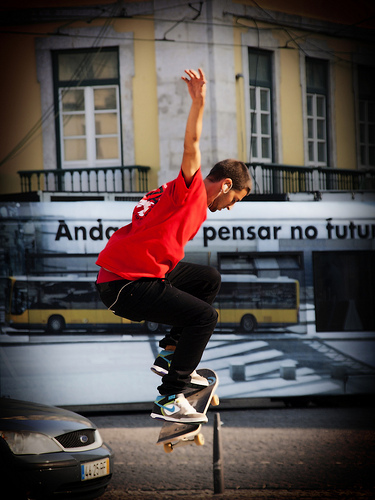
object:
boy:
[94, 65, 257, 425]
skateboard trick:
[140, 351, 234, 492]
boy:
[89, 66, 255, 455]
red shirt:
[95, 167, 209, 278]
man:
[92, 63, 264, 451]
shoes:
[147, 347, 211, 426]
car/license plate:
[76, 454, 112, 480]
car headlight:
[1, 426, 64, 457]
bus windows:
[230, 285, 290, 303]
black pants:
[95, 261, 220, 393]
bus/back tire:
[238, 311, 258, 334]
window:
[54, 82, 124, 189]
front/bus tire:
[45, 312, 67, 335]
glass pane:
[61, 113, 86, 134]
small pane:
[95, 111, 119, 136]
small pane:
[93, 135, 121, 158]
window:
[55, 83, 123, 166]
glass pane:
[61, 90, 85, 112]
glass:
[96, 135, 120, 161]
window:
[48, 45, 125, 190]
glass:
[248, 87, 256, 110]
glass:
[260, 87, 270, 112]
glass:
[258, 111, 271, 136]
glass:
[261, 134, 271, 159]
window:
[248, 85, 275, 162]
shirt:
[93, 166, 208, 279]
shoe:
[150, 392, 209, 424]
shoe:
[151, 347, 210, 388]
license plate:
[80, 456, 110, 481]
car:
[0, 395, 116, 498]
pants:
[94, 261, 222, 397]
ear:
[220, 177, 232, 194]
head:
[203, 157, 250, 212]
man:
[95, 67, 253, 425]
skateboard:
[154, 367, 220, 451]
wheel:
[162, 440, 174, 453]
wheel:
[195, 434, 206, 447]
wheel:
[211, 394, 220, 407]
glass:
[89, 86, 119, 111]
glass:
[316, 95, 326, 118]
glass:
[317, 117, 325, 139]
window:
[302, 91, 329, 165]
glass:
[317, 140, 327, 163]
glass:
[306, 116, 315, 139]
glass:
[305, 95, 315, 116]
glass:
[261, 112, 271, 137]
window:
[244, 84, 276, 163]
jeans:
[97, 259, 222, 394]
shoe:
[134, 362, 203, 416]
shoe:
[145, 334, 209, 389]